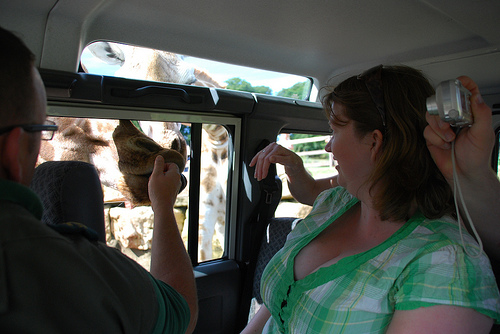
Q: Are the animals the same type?
A: Yes, all the animals are giraffes.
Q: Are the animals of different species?
A: No, all the animals are giraffes.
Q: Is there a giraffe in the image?
A: Yes, there is a giraffe.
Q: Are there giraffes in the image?
A: Yes, there is a giraffe.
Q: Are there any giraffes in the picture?
A: Yes, there is a giraffe.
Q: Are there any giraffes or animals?
A: Yes, there is a giraffe.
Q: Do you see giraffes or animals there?
A: Yes, there is a giraffe.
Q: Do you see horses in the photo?
A: No, there are no horses.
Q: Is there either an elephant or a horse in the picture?
A: No, there are no horses or elephants.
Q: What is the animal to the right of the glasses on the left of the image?
A: The animal is a giraffe.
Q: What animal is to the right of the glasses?
A: The animal is a giraffe.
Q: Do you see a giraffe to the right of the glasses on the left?
A: Yes, there is a giraffe to the right of the glasses.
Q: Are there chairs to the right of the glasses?
A: No, there is a giraffe to the right of the glasses.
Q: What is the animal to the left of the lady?
A: The animal is a giraffe.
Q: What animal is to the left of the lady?
A: The animal is a giraffe.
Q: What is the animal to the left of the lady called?
A: The animal is a giraffe.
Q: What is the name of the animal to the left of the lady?
A: The animal is a giraffe.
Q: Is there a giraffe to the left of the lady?
A: Yes, there is a giraffe to the left of the lady.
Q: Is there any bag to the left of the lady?
A: No, there is a giraffe to the left of the lady.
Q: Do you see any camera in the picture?
A: Yes, there is a camera.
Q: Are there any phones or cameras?
A: Yes, there is a camera.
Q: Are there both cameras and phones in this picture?
A: No, there is a camera but no phones.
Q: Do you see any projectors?
A: No, there are no projectors.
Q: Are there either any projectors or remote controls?
A: No, there are no projectors or remote controls.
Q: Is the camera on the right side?
A: Yes, the camera is on the right of the image.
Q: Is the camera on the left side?
A: No, the camera is on the right of the image.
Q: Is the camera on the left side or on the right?
A: The camera is on the right of the image.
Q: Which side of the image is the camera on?
A: The camera is on the right of the image.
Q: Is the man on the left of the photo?
A: Yes, the man is on the left of the image.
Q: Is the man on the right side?
A: No, the man is on the left of the image.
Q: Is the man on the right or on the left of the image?
A: The man is on the left of the image.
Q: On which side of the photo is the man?
A: The man is on the left of the image.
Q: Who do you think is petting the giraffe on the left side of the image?
A: The man is petting the giraffe.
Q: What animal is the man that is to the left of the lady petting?
A: The man is petting the giraffe.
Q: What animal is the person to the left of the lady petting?
A: The man is petting the giraffe.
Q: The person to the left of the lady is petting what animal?
A: The man is petting the giraffe.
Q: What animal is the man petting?
A: The man is petting the giraffe.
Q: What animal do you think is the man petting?
A: The man is petting the giraffe.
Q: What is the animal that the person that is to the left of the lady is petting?
A: The animal is a giraffe.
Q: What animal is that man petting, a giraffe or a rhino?
A: The man is petting a giraffe.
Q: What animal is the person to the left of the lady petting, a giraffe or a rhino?
A: The man is petting a giraffe.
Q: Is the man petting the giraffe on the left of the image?
A: Yes, the man is petting the giraffe.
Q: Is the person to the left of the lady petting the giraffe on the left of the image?
A: Yes, the man is petting the giraffe.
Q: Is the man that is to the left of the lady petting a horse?
A: No, the man is petting the giraffe.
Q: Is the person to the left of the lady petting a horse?
A: No, the man is petting the giraffe.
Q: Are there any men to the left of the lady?
A: Yes, there is a man to the left of the lady.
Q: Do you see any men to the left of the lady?
A: Yes, there is a man to the left of the lady.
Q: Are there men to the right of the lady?
A: No, the man is to the left of the lady.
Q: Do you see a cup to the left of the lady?
A: No, there is a man to the left of the lady.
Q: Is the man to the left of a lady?
A: Yes, the man is to the left of a lady.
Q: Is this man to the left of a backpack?
A: No, the man is to the left of a lady.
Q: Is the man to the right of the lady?
A: No, the man is to the left of the lady.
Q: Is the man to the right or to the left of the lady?
A: The man is to the left of the lady.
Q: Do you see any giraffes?
A: Yes, there is a giraffe.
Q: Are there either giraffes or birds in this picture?
A: Yes, there is a giraffe.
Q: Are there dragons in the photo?
A: No, there are no dragons.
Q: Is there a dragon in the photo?
A: No, there are no dragons.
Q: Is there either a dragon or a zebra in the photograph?
A: No, there are no dragons or zebras.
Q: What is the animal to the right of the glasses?
A: The animal is a giraffe.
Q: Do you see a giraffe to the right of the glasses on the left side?
A: Yes, there is a giraffe to the right of the glasses.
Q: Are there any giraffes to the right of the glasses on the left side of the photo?
A: Yes, there is a giraffe to the right of the glasses.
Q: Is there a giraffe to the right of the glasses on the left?
A: Yes, there is a giraffe to the right of the glasses.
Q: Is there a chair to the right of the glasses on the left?
A: No, there is a giraffe to the right of the glasses.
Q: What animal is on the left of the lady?
A: The animal is a giraffe.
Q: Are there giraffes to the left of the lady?
A: Yes, there is a giraffe to the left of the lady.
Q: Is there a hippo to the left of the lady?
A: No, there is a giraffe to the left of the lady.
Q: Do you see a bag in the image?
A: No, there are no bags.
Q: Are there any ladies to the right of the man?
A: Yes, there is a lady to the right of the man.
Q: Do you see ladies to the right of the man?
A: Yes, there is a lady to the right of the man.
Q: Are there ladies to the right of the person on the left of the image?
A: Yes, there is a lady to the right of the man.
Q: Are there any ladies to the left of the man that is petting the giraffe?
A: No, the lady is to the right of the man.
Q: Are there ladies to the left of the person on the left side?
A: No, the lady is to the right of the man.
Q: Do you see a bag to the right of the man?
A: No, there is a lady to the right of the man.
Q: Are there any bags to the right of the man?
A: No, there is a lady to the right of the man.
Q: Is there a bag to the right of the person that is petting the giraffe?
A: No, there is a lady to the right of the man.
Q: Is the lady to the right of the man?
A: Yes, the lady is to the right of the man.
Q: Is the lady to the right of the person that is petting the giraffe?
A: Yes, the lady is to the right of the man.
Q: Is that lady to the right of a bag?
A: No, the lady is to the right of the man.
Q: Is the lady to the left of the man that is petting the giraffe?
A: No, the lady is to the right of the man.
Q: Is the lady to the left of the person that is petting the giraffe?
A: No, the lady is to the right of the man.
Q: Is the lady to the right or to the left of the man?
A: The lady is to the right of the man.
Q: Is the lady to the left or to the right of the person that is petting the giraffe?
A: The lady is to the right of the man.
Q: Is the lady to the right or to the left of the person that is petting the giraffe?
A: The lady is to the right of the man.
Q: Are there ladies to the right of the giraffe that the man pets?
A: Yes, there is a lady to the right of the giraffe.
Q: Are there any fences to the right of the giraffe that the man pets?
A: No, there is a lady to the right of the giraffe.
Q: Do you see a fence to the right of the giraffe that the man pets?
A: No, there is a lady to the right of the giraffe.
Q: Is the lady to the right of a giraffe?
A: Yes, the lady is to the right of a giraffe.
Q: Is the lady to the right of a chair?
A: No, the lady is to the right of a giraffe.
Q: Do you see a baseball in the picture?
A: No, there are no baseballs.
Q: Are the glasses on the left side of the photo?
A: Yes, the glasses are on the left of the image.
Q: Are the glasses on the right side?
A: No, the glasses are on the left of the image.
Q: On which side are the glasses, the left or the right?
A: The glasses are on the left of the image.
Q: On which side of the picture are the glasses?
A: The glasses are on the left of the image.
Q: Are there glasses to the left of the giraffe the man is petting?
A: Yes, there are glasses to the left of the giraffe.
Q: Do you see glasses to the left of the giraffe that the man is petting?
A: Yes, there are glasses to the left of the giraffe.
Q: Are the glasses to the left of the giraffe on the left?
A: Yes, the glasses are to the left of the giraffe.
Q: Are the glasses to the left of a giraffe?
A: Yes, the glasses are to the left of a giraffe.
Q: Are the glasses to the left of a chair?
A: No, the glasses are to the left of a giraffe.